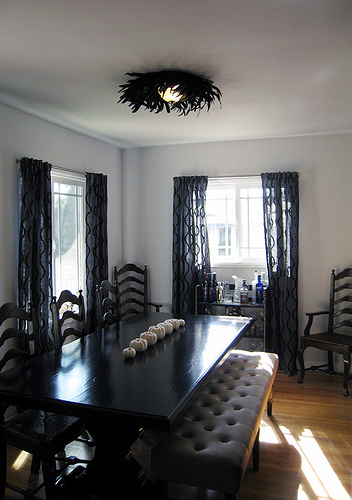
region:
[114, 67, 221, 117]
a wreath around a light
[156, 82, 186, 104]
a light in the ceiling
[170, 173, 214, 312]
a patterned black curtain in the window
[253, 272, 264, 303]
a blue bottle on a shelf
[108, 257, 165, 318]
a wooden chair in a corner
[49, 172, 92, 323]
a dining room window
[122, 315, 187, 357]
a row of pumpkins on a table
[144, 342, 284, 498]
a padded bench at a dining room table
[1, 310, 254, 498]
a dark brown dining table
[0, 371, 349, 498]
a light colored hardwood floor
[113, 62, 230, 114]
Light fixture that has black feathers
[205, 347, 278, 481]
long bench that sits at a table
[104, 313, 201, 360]
pumpkins sitting on a table as a decoration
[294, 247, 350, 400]
chair placed in a corner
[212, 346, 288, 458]
buttons decorating a stool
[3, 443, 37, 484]
ray of sunshine on the floor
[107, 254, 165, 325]
chair sitting in a corner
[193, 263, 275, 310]
bottles of alcohol sitting on a table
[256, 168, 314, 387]
black sheer drapes hanging from the wall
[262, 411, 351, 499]
light reflecting off the floor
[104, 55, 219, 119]
Light on the ceiling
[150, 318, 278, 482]
Bench under a table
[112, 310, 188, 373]
Onions on a table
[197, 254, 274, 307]
Liquor on a cart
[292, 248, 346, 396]
chair against a wall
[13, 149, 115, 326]
curtains on a window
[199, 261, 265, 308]
Liquor on a cart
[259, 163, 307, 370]
black curtain on the window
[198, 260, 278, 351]
liquor on a tea cart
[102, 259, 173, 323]
Chair near the wall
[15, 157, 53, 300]
long black cloth curtain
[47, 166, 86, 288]
large white window on house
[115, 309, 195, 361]
row of small white pumpkins on table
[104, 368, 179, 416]
black wooden table top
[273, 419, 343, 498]
sunlight shining on hardwood floor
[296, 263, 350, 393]
brown wooden chair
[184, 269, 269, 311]
glass alcohol bottles sitting on shelf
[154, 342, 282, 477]
beige bench beside table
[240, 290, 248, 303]
company label on side of whisky bottle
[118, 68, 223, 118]
a black light fixture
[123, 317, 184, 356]
white guords on a table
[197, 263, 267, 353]
a shelf full of liquor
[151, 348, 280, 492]
a padded bench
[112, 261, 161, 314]
a chair is in the corner of the room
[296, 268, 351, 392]
a chair is in the corner of the room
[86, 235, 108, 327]
a black curtain on a window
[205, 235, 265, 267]
a window in a room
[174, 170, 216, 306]
a decorative black curtain panel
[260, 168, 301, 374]
a decorative black curtain panel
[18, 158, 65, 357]
a decorative black curtain panel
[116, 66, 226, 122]
a black decorated ceiling light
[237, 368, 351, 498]
brown hardwood floor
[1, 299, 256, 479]
a black dining room table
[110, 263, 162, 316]
a black dining room chair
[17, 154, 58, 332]
long black curtains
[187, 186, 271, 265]
a window of a home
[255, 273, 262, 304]
a tall blue bottle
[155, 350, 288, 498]
a long dining room bench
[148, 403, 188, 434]
Edge of a table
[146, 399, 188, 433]
Edge of a table